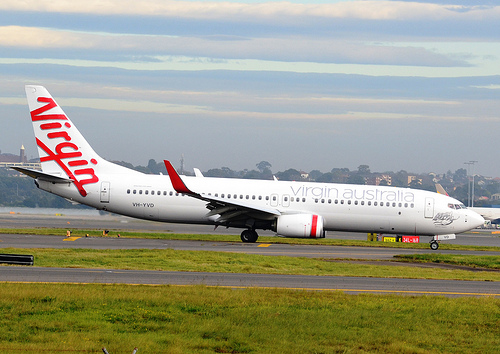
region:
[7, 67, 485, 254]
white and red airplane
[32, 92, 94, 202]
red lettering on the airplane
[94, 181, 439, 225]
two doors on the airplane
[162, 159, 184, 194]
red upturned tip of the airplane wing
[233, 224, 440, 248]
wheels on the airplane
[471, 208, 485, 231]
nose of the airplane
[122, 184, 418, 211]
line of windows on the airplane's side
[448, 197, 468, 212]
windows on the cockpit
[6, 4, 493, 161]
lines of clouds in the sky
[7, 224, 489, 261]
runway plane is stopped on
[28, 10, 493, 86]
clouds in the sky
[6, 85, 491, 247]
a white and red airplane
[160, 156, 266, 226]
the wing on the airplane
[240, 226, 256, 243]
tires on the airplane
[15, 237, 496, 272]
grass in front of the airplane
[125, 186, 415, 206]
windows on the airplane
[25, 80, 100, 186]
the tail wing on the plane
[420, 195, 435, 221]
the door on the airplane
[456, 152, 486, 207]
poles in the background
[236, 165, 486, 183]
trees and buildings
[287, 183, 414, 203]
Virgin Australia written on side of passenger jet plane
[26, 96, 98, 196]
Virgin airline logo on tail of passenger jet plane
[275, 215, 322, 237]
Jet engine under wing of passenger plane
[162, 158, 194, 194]
Red winglet on top of airplane wing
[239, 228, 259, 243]
Back landing gear of airplane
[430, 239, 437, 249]
Front landing gear of airplane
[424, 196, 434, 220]
Front door on passenger jet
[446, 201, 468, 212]
Windshields on jet plane cockpit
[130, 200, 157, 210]
Code VH-YYD written on side of passenger airplane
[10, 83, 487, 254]
Virgin airline jet plane on runway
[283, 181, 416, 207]
the brand of the airline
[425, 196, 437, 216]
service door of the airplance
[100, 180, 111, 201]
rear door of the airplane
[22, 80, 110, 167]
the tail fin of the airplane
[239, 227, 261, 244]
rear landing gear of the airplane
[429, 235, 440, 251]
front landing gear of the plane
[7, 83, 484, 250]
a jet on the taxi way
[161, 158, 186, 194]
the bent upward wing tip of the plane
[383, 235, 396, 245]
yellow sign at the airport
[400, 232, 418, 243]
orange sign at the airport